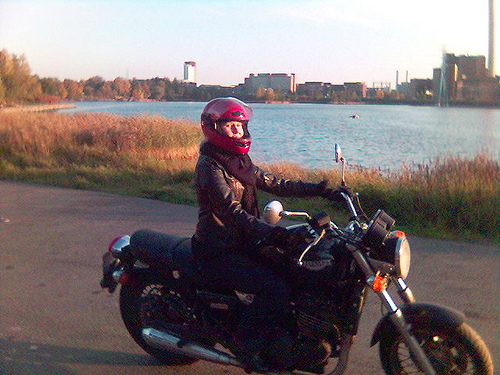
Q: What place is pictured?
A: It is a road.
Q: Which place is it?
A: It is a road.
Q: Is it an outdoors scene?
A: Yes, it is outdoors.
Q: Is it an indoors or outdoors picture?
A: It is outdoors.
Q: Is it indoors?
A: No, it is outdoors.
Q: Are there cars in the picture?
A: No, there are no cars.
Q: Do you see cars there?
A: No, there are no cars.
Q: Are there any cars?
A: No, there are no cars.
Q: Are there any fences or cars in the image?
A: No, there are no cars or fences.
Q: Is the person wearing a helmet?
A: Yes, the person is wearing a helmet.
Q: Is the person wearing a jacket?
A: Yes, the person is wearing a jacket.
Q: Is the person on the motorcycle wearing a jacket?
A: Yes, the person is wearing a jacket.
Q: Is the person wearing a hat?
A: No, the person is wearing a jacket.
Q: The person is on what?
A: The person is on the motorcycle.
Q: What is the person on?
A: The person is on the motorcycle.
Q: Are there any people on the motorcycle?
A: Yes, there is a person on the motorcycle.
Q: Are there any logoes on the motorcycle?
A: No, there is a person on the motorcycle.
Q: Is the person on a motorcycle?
A: Yes, the person is on a motorcycle.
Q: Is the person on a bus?
A: No, the person is on a motorcycle.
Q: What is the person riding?
A: The person is riding a motorcycle.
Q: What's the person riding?
A: The person is riding a motorcycle.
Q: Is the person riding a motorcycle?
A: Yes, the person is riding a motorcycle.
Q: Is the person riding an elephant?
A: No, the person is riding a motorcycle.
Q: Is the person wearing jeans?
A: Yes, the person is wearing jeans.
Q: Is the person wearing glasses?
A: No, the person is wearing jeans.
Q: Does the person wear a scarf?
A: Yes, the person wears a scarf.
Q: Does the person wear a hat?
A: No, the person wears a scarf.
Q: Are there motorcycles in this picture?
A: Yes, there is a motorcycle.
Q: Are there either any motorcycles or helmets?
A: Yes, there is a motorcycle.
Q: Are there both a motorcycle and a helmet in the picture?
A: Yes, there are both a motorcycle and a helmet.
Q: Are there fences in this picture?
A: No, there are no fences.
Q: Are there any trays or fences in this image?
A: No, there are no fences or trays.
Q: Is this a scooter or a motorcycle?
A: This is a motorcycle.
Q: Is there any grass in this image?
A: Yes, there is grass.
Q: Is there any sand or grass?
A: Yes, there is grass.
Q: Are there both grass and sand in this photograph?
A: No, there is grass but no sand.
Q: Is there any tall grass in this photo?
A: Yes, there is tall grass.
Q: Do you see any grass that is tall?
A: Yes, there is grass that is tall.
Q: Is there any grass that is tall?
A: Yes, there is grass that is tall.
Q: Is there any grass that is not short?
A: Yes, there is tall grass.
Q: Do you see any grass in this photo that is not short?
A: Yes, there is tall grass.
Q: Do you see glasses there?
A: No, there are no glasses.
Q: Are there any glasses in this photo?
A: No, there are no glasses.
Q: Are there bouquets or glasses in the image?
A: No, there are no glasses or bouquets.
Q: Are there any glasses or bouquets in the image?
A: No, there are no glasses or bouquets.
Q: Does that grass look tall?
A: Yes, the grass is tall.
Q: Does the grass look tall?
A: Yes, the grass is tall.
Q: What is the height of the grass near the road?
A: The grass is tall.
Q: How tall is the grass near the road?
A: The grass is tall.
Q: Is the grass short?
A: No, the grass is tall.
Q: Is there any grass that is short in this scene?
A: No, there is grass but it is tall.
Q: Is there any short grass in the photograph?
A: No, there is grass but it is tall.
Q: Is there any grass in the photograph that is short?
A: No, there is grass but it is tall.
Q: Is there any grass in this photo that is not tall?
A: No, there is grass but it is tall.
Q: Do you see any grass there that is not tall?
A: No, there is grass but it is tall.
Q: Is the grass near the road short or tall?
A: The grass is tall.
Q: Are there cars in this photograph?
A: No, there are no cars.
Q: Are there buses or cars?
A: No, there are no cars or buses.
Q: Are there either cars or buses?
A: No, there are no cars or buses.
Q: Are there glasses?
A: No, there are no glasses.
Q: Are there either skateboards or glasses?
A: No, there are no glasses or skateboards.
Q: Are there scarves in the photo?
A: Yes, there is a scarf.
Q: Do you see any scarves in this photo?
A: Yes, there is a scarf.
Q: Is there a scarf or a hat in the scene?
A: Yes, there is a scarf.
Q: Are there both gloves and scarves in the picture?
A: Yes, there are both a scarf and gloves.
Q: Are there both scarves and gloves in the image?
A: Yes, there are both a scarf and gloves.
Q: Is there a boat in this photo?
A: No, there are no boats.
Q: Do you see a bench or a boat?
A: No, there are no boats or benches.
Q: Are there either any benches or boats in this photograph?
A: No, there are no boats or benches.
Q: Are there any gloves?
A: Yes, there are gloves.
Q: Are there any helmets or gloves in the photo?
A: Yes, there are gloves.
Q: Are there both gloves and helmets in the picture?
A: Yes, there are both gloves and a helmet.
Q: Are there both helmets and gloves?
A: Yes, there are both gloves and a helmet.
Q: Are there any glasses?
A: No, there are no glasses.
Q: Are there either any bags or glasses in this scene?
A: No, there are no glasses or bags.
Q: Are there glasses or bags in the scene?
A: No, there are no glasses or bags.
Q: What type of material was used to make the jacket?
A: The jacket is made of leather.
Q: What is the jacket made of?
A: The jacket is made of leather.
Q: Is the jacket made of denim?
A: No, the jacket is made of leather.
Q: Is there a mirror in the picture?
A: Yes, there is a mirror.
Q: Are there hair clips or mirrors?
A: Yes, there is a mirror.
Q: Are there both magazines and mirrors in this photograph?
A: No, there is a mirror but no magazines.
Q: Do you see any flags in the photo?
A: No, there are no flags.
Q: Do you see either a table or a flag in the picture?
A: No, there are no flags or tables.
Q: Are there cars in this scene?
A: No, there are no cars.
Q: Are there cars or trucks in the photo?
A: No, there are no cars or trucks.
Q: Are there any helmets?
A: Yes, there is a helmet.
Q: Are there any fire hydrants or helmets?
A: Yes, there is a helmet.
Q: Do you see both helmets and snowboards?
A: No, there is a helmet but no snowboards.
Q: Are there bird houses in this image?
A: No, there are no bird houses.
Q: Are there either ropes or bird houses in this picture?
A: No, there are no bird houses or ropes.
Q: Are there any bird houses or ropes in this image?
A: No, there are no bird houses or ropes.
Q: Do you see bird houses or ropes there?
A: No, there are no bird houses or ropes.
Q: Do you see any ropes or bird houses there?
A: No, there are no bird houses or ropes.